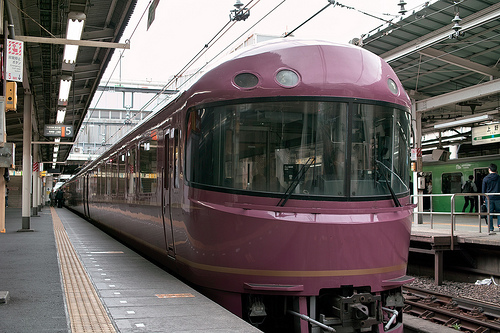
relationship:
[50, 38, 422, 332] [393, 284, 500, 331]
train on tracks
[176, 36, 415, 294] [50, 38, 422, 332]
front of train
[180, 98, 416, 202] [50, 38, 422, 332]
windshield of train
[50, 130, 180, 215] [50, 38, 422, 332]
windows of train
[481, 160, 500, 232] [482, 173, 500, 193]
man wearing blue shirt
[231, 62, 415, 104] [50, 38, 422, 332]
headlights on train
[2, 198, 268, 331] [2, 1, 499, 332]
unloading platform at train station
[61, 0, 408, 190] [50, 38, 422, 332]
power lines for train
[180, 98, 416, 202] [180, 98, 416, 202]
windshield on windshield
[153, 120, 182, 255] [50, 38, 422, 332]
door of train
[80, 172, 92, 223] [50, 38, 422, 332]
door of train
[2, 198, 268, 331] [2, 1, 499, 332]
unloading platform for train station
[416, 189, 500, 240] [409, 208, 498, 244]
guardrail on platform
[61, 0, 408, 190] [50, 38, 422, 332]
power lines above train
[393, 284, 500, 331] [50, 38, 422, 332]
tracks for train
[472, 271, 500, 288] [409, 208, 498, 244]
trash below platform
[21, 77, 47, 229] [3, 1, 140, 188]
steel beams holding up canopy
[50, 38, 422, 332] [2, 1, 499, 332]
train in train station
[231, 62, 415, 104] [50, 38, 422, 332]
headlights of train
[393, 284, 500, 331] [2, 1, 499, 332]
tracks at train station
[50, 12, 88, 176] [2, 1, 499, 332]
lights at train station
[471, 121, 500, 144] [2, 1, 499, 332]
sign at train station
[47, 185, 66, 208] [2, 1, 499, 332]
passengers at train station